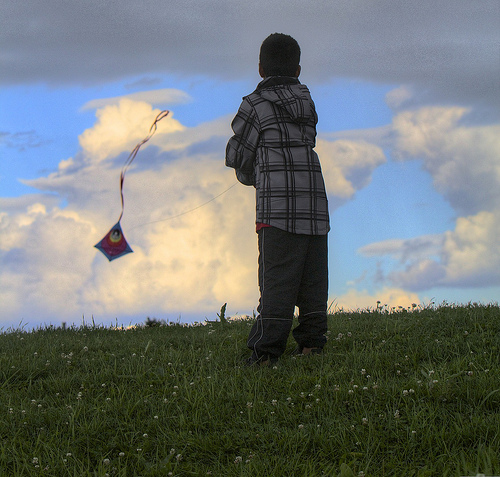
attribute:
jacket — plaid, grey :
[220, 70, 331, 242]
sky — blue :
[0, 1, 497, 333]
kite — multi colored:
[90, 212, 140, 262]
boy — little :
[224, 20, 346, 377]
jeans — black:
[246, 222, 330, 355]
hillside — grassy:
[0, 304, 497, 476]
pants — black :
[243, 222, 329, 357]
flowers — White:
[0, 325, 497, 476]